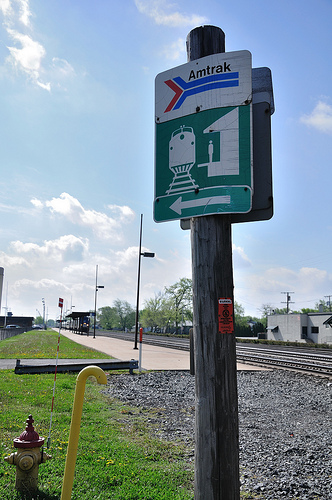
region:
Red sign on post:
[210, 294, 241, 340]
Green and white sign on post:
[147, 102, 266, 229]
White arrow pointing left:
[162, 193, 237, 215]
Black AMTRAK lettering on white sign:
[186, 63, 231, 81]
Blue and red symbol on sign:
[158, 70, 242, 116]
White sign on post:
[151, 48, 256, 129]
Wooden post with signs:
[184, 22, 243, 499]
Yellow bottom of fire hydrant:
[3, 445, 53, 493]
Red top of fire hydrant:
[10, 410, 46, 451]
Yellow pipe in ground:
[55, 362, 113, 499]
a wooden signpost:
[185, 23, 239, 498]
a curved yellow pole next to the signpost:
[61, 363, 107, 498]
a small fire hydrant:
[4, 412, 52, 489]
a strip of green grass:
[0, 326, 194, 498]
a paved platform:
[51, 326, 272, 371]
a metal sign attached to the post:
[152, 50, 273, 229]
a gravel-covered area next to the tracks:
[99, 370, 330, 499]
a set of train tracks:
[87, 326, 331, 378]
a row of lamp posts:
[60, 212, 155, 349]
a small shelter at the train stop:
[67, 310, 95, 334]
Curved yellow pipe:
[59, 364, 116, 498]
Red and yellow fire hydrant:
[4, 411, 55, 495]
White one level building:
[265, 308, 330, 349]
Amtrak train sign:
[150, 48, 255, 123]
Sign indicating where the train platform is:
[149, 107, 259, 219]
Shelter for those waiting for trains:
[68, 308, 96, 339]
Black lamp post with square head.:
[129, 213, 159, 356]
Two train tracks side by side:
[240, 341, 328, 382]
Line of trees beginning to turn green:
[99, 286, 191, 339]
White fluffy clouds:
[6, 191, 150, 298]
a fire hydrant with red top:
[3, 412, 55, 496]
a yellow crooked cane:
[59, 363, 110, 498]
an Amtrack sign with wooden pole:
[153, 23, 274, 499]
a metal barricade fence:
[12, 357, 138, 374]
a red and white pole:
[46, 295, 64, 449]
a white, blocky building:
[262, 288, 331, 345]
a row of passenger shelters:
[62, 310, 94, 336]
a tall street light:
[130, 212, 157, 351]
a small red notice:
[215, 295, 234, 334]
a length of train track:
[84, 324, 331, 381]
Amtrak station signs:
[146, 46, 256, 223]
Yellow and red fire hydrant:
[3, 411, 54, 495]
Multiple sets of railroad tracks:
[89, 314, 330, 378]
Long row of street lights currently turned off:
[51, 211, 156, 350]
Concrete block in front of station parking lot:
[0, 318, 34, 340]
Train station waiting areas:
[53, 308, 94, 336]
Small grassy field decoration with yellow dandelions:
[0, 314, 185, 498]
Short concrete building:
[261, 305, 331, 347]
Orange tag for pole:
[212, 291, 234, 336]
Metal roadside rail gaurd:
[11, 354, 141, 380]